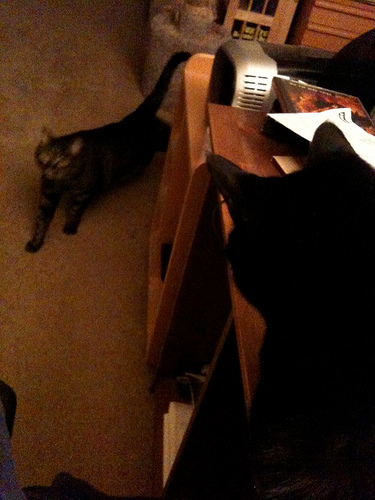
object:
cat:
[23, 50, 190, 253]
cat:
[201, 121, 373, 498]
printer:
[272, 76, 372, 135]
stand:
[141, 50, 219, 368]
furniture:
[143, 51, 277, 499]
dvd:
[206, 36, 278, 111]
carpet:
[0, 0, 171, 499]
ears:
[204, 149, 268, 213]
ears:
[309, 120, 353, 160]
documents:
[162, 400, 196, 488]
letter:
[267, 106, 375, 168]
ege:
[206, 102, 258, 139]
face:
[33, 122, 83, 185]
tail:
[136, 50, 191, 115]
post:
[141, 0, 233, 111]